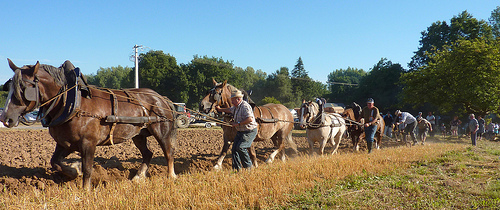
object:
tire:
[175, 114, 190, 128]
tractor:
[171, 103, 191, 128]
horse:
[197, 77, 299, 171]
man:
[394, 108, 420, 146]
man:
[215, 90, 259, 173]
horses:
[344, 102, 386, 154]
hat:
[230, 90, 243, 98]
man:
[355, 97, 380, 154]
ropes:
[88, 81, 233, 128]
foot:
[48, 162, 80, 181]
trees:
[143, 49, 327, 109]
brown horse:
[0, 57, 182, 192]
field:
[0, 115, 500, 209]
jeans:
[230, 129, 258, 170]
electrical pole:
[131, 44, 146, 89]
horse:
[298, 99, 346, 157]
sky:
[1, 0, 499, 81]